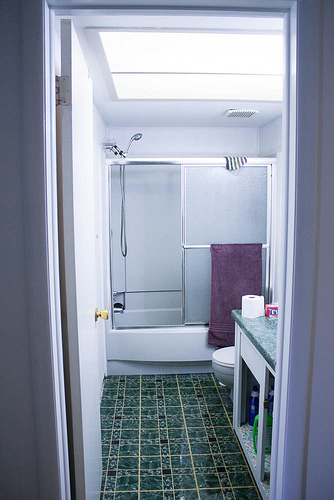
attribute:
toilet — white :
[211, 345, 233, 397]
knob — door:
[93, 305, 110, 322]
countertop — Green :
[231, 307, 278, 370]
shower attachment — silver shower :
[113, 133, 142, 256]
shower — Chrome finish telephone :
[99, 129, 145, 257]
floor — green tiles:
[101, 367, 255, 498]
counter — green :
[229, 278, 289, 385]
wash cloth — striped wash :
[225, 153, 250, 171]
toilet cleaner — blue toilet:
[249, 387, 260, 423]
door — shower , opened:
[106, 167, 294, 336]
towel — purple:
[210, 244, 261, 333]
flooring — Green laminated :
[128, 385, 185, 417]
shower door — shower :
[179, 157, 269, 327]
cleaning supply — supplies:
[248, 385, 260, 425]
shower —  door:
[102, 123, 277, 361]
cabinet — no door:
[233, 323, 274, 497]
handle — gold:
[93, 307, 109, 320]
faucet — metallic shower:
[108, 130, 145, 159]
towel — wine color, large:
[207, 243, 261, 345]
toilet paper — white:
[239, 293, 266, 316]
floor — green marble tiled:
[202, 444, 221, 465]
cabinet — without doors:
[222, 314, 279, 491]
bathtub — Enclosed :
[102, 318, 246, 368]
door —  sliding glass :
[96, 127, 286, 327]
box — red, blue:
[265, 303, 277, 314]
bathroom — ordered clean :
[97, 23, 276, 495]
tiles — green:
[136, 437, 166, 449]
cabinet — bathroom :
[237, 354, 271, 482]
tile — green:
[111, 386, 167, 420]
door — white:
[57, 18, 104, 498]